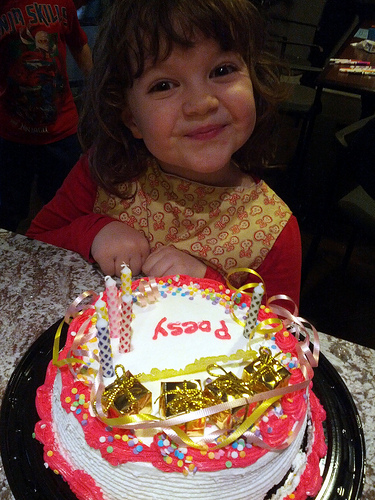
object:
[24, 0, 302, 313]
girl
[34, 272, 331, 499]
cake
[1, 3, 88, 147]
shirt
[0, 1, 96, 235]
child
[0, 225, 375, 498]
table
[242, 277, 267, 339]
candle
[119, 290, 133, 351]
candle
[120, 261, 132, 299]
candle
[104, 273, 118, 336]
candle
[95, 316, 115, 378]
candle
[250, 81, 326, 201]
chair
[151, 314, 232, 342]
word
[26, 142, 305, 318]
shirt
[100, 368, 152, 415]
box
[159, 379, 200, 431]
box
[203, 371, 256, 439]
box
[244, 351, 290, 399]
box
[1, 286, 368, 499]
platter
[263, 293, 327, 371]
ribbon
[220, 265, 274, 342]
ribbon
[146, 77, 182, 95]
eye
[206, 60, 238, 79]
eye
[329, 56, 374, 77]
pens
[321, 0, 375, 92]
desk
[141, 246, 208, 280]
hand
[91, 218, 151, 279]
hand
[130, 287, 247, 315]
sprinkles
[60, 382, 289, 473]
sprinkles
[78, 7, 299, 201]
hair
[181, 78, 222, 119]
nose